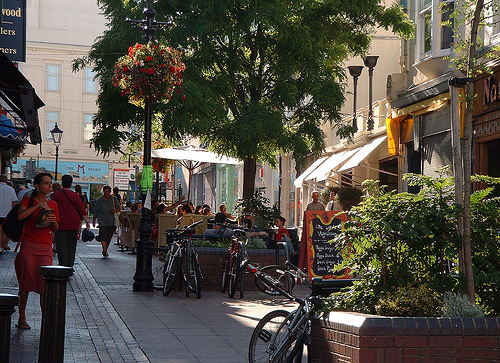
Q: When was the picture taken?
A: During the day.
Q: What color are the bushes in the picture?
A: Green.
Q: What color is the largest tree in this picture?
A: Green.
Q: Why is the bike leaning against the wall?
A: To keep from falling.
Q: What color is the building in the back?
A: Beige.